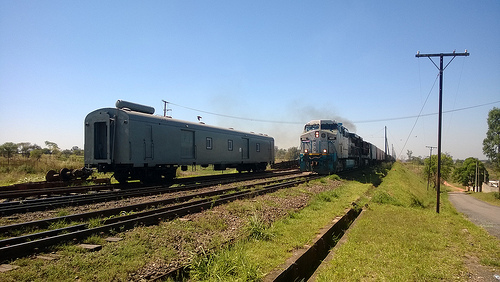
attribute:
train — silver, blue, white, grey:
[296, 110, 389, 171]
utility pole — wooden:
[416, 49, 466, 222]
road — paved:
[436, 171, 499, 240]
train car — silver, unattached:
[83, 99, 280, 188]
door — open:
[94, 122, 109, 160]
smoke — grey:
[333, 116, 358, 135]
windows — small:
[203, 137, 265, 153]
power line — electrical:
[352, 36, 496, 159]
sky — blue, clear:
[1, 1, 500, 154]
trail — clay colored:
[436, 178, 468, 192]